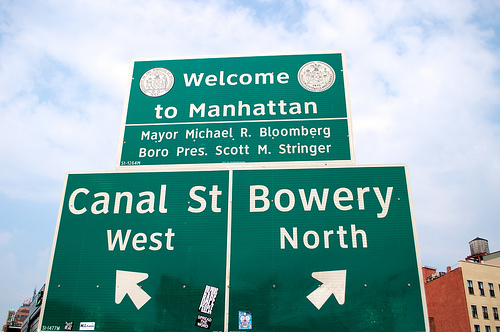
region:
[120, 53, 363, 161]
green sign above other sign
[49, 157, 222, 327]
arrow points to canal st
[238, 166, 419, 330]
arrow points to bowery street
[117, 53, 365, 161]
sign is welcoming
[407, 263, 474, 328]
red brick building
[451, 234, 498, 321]
white building by train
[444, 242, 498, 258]
water tower above building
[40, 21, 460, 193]
white clouds in blue sky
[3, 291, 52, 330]
buildings in the distance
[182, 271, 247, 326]
stickers on green sign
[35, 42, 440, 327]
3 green signs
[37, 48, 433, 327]
signs have white letters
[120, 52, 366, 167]
top sign has "Welcome to Manhattan" written in big letters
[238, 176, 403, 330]
sign on the right reads "Bowery North"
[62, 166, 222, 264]
sign on the left reads "Canal St West"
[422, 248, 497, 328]
a tan and red building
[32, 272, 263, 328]
road signs have stickers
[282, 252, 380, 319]
arrow points up and right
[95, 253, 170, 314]
arrow points up and left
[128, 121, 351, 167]
smaller letters read "Mayor Michael R. Bloomberg Boro Pres. Scott M. Stringer"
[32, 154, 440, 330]
a green and white sign with arrows pointing in opposite directions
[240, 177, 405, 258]
Bowery North written in white lettering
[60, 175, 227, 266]
Canal St West written in white lettering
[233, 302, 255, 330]
a blue, white, and pink sticker of an animated figure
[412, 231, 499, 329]
a brick building complex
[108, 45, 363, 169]
a sign welcoming people to Manhattan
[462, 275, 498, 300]
three windows on a brick building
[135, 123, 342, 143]
the words "mayor Michael R. Bloomberg" written in white lettering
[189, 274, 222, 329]
two black and white stickers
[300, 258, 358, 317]
a white arrow pointing at a diagonal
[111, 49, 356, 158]
green metal sign to welcome visitors to Manhattan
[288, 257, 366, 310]
white arrow pointing to the right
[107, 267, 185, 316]
white arrow pointing to the left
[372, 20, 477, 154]
blue sky with lots of clouds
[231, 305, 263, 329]
blue sticker on green sign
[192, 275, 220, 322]
white sticker on green sign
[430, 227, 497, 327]
building on the right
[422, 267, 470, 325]
side of the building is red brick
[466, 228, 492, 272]
water tower on top of building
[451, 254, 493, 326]
lots of windows on the tan side of the building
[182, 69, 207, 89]
the white letter W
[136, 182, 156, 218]
the white letter A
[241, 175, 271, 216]
the white letter B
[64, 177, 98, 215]
the white letter C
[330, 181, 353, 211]
the white letter E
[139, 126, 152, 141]
the white letter M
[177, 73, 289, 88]
the white word Welcome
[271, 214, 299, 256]
the white letter N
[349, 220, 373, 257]
the white letter H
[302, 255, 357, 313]
white arrow pointing right